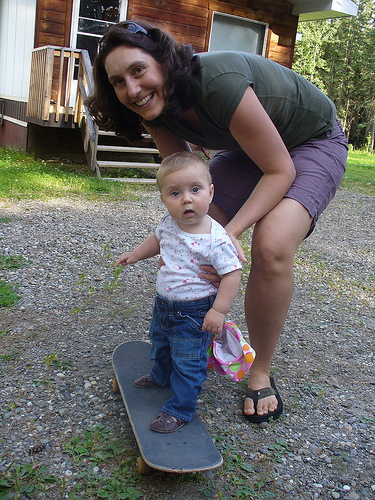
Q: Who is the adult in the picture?
A: A woman.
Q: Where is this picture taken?
A: Outside of a home.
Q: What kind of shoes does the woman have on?
A: Flip flops.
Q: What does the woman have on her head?
A: Sunglasses.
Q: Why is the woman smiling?
A: She is excited to be holding the child on the skateboard.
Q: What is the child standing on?
A: A skateboard.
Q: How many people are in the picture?
A: Two.